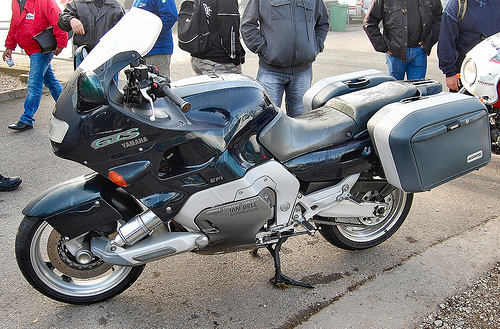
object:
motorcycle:
[14, 26, 494, 306]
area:
[2, 0, 500, 329]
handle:
[158, 83, 191, 113]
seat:
[258, 81, 418, 163]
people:
[2, 1, 499, 130]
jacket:
[4, 0, 69, 55]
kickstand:
[249, 236, 315, 290]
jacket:
[362, 0, 443, 62]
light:
[49, 114, 70, 144]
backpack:
[178, 1, 214, 54]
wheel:
[14, 201, 147, 308]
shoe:
[0, 173, 21, 192]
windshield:
[79, 7, 163, 95]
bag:
[365, 90, 492, 193]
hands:
[383, 41, 429, 54]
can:
[3, 53, 16, 67]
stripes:
[455, 0, 467, 21]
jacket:
[437, 0, 500, 78]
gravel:
[422, 307, 466, 329]